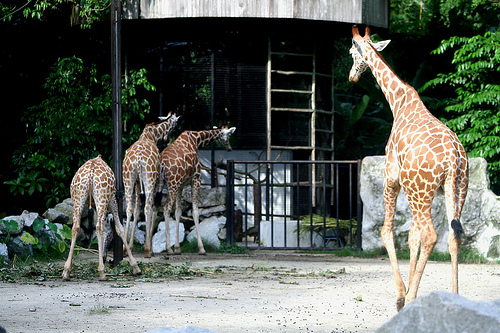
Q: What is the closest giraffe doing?
A: Walking.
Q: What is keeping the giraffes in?
A: Fence.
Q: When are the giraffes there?
A: Daytime.